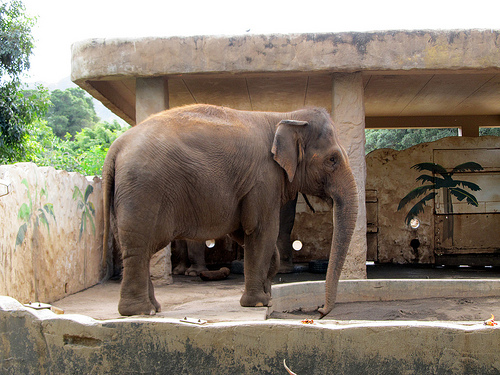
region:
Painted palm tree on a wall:
[71, 183, 104, 241]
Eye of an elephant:
[328, 153, 338, 163]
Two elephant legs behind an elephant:
[167, 235, 218, 282]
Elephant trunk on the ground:
[318, 194, 368, 316]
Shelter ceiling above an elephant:
[66, 38, 498, 74]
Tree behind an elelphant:
[0, 10, 35, 163]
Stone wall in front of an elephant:
[9, 297, 499, 373]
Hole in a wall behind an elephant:
[290, 234, 307, 251]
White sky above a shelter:
[91, 6, 494, 24]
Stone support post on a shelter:
[326, 72, 379, 277]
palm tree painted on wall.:
[394, 152, 486, 253]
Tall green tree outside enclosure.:
[1, 4, 42, 159]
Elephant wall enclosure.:
[13, 161, 108, 293]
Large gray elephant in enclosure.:
[100, 102, 360, 320]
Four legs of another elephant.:
[179, 210, 300, 277]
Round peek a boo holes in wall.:
[202, 217, 421, 252]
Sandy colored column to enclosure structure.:
[332, 80, 366, 277]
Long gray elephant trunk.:
[315, 172, 362, 317]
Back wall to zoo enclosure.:
[370, 135, 491, 268]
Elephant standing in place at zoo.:
[100, 102, 365, 314]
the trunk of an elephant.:
[316, 165, 361, 308]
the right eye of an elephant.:
[320, 150, 344, 178]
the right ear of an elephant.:
[266, 117, 309, 188]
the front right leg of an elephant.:
[239, 214, 291, 316]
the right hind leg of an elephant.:
[106, 209, 174, 320]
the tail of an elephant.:
[93, 140, 125, 270]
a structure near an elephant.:
[66, 37, 498, 276]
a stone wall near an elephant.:
[0, 159, 110, 305]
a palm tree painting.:
[393, 156, 489, 246]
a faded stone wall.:
[4, 290, 498, 373]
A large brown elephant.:
[100, 99, 360, 313]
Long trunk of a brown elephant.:
[315, 174, 358, 314]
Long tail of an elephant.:
[97, 150, 112, 265]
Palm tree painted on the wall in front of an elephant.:
[397, 161, 481, 243]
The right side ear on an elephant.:
[269, 118, 310, 182]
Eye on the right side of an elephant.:
[325, 154, 337, 166]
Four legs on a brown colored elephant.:
[108, 209, 281, 318]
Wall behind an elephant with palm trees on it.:
[0, 159, 113, 310]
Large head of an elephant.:
[280, 107, 347, 211]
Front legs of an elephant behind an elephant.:
[175, 236, 207, 276]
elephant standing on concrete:
[75, 105, 383, 329]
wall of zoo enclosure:
[25, 169, 101, 296]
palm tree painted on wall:
[397, 150, 484, 230]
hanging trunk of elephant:
[305, 186, 370, 319]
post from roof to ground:
[315, 61, 380, 306]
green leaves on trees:
[35, 105, 110, 167]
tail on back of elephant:
[80, 140, 136, 277]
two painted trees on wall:
[13, 176, 98, 288]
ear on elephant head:
[265, 113, 310, 189]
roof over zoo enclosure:
[376, 41, 463, 92]